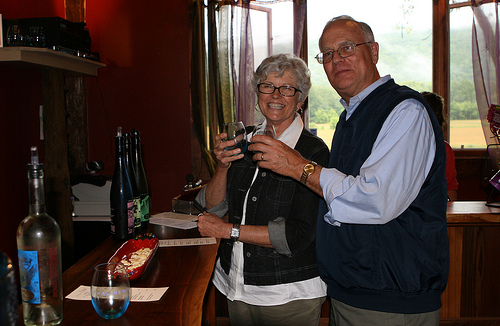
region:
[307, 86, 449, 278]
He is wearing a blue vest.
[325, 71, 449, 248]
He is wearing a blue shirt.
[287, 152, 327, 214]
He is weaing a gold watch.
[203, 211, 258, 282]
She is wearing a silver watch.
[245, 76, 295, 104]
She has glasses on.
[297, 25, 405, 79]
He is wearing glasses.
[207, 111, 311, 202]
They are holding glasses.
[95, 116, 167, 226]
The bottles are on the counter.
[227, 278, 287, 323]
She is wearing tan pants.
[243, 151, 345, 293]
She has a brown jacket on.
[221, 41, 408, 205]
An elderly couple is drinking wine.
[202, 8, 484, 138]
The couple stands in front of a window.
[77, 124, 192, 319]
Wine bottles stand in a row.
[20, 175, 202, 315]
The wine sits upon a bar table.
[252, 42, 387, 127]
The man and woman both wear glasses.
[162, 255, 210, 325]
The bar furniture is wooden.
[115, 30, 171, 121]
The walls are red.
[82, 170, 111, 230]
A cash register is behind the bar.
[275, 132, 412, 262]
The man and woman are wearing sweaters.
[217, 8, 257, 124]
The sheer curtains are multi-colored.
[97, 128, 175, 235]
three bottles standing together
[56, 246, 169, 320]
glass on the bar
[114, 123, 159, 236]
bottle of wines are black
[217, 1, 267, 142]
blinds on the window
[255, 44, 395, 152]
couple wears glasses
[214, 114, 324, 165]
holding glasses of wine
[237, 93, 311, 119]
woman has a big smile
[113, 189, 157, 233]
wine labels are pink, yellow and green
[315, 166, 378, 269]
man has his sleeve rolled up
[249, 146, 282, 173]
man is wearing a wedding band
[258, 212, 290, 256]
edge of a sleeve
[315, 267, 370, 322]
edge of a jacket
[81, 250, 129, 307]
part of a glass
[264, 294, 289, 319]
part of a trouser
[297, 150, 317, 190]
part of a watch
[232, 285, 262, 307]
edge of a shirt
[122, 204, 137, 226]
part of a bottle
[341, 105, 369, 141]
part of a sweater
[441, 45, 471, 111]
part of a window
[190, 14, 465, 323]
an elderly couple drinking wine together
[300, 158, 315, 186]
a man's wrist watch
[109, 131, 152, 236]
wine bottles sitting on a shelf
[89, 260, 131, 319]
an empty glass sitting on a shelf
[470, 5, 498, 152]
a sheer window drapery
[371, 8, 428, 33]
a hazy sky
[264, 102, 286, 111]
a woman's mouth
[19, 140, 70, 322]
a glass bottle sitting on a shelf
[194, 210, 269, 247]
a woman's arm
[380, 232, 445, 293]
a man's vest